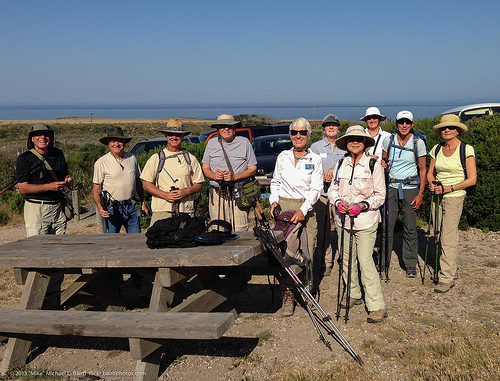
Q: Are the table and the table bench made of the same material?
A: Yes, both the table and the bench are made of wood.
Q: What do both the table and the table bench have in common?
A: The material, both the table and the bench are wooden.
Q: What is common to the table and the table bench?
A: The material, both the table and the bench are wooden.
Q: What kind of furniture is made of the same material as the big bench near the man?
A: The table is made of the same material as the bench.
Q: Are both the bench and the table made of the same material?
A: Yes, both the bench and the table are made of wood.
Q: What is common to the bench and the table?
A: The material, both the bench and the table are wooden.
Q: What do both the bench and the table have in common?
A: The material, both the bench and the table are wooden.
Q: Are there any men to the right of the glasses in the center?
A: Yes, there is a man to the right of the glasses.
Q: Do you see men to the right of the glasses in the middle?
A: Yes, there is a man to the right of the glasses.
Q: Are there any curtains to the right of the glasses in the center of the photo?
A: No, there is a man to the right of the glasses.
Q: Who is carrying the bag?
A: The man is carrying the bag.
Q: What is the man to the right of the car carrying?
A: The man is carrying a bag.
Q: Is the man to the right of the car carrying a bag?
A: Yes, the man is carrying a bag.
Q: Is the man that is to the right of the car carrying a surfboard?
A: No, the man is carrying a bag.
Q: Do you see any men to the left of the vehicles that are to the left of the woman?
A: Yes, there is a man to the left of the vehicles.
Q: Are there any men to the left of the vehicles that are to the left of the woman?
A: Yes, there is a man to the left of the vehicles.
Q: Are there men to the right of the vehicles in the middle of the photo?
A: No, the man is to the left of the vehicles.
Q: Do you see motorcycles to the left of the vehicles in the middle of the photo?
A: No, there is a man to the left of the vehicles.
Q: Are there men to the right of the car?
A: Yes, there is a man to the right of the car.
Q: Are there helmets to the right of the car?
A: No, there is a man to the right of the car.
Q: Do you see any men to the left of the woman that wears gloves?
A: Yes, there is a man to the left of the woman.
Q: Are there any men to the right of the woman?
A: No, the man is to the left of the woman.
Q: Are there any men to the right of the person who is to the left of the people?
A: No, the man is to the left of the woman.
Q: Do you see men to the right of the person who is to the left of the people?
A: No, the man is to the left of the woman.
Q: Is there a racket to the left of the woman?
A: No, there is a man to the left of the woman.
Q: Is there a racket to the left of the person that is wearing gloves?
A: No, there is a man to the left of the woman.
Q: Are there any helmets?
A: No, there are no helmets.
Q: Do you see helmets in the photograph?
A: No, there are no helmets.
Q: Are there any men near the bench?
A: Yes, there is a man near the bench.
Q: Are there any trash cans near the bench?
A: No, there is a man near the bench.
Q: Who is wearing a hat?
A: The man is wearing a hat.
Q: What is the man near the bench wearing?
A: The man is wearing a hat.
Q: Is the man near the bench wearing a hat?
A: Yes, the man is wearing a hat.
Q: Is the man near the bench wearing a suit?
A: No, the man is wearing a hat.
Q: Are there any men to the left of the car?
A: Yes, there is a man to the left of the car.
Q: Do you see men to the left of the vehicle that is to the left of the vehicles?
A: Yes, there is a man to the left of the car.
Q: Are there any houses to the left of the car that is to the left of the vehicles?
A: No, there is a man to the left of the car.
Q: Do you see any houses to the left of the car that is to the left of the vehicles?
A: No, there is a man to the left of the car.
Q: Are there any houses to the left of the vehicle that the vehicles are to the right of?
A: No, there is a man to the left of the car.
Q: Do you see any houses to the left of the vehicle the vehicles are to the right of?
A: No, there is a man to the left of the car.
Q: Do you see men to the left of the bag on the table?
A: Yes, there is a man to the left of the bag.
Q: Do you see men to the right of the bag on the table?
A: No, the man is to the left of the bag.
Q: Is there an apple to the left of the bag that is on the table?
A: No, there is a man to the left of the bag.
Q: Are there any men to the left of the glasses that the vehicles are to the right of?
A: Yes, there is a man to the left of the glasses.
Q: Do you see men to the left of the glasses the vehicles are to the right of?
A: Yes, there is a man to the left of the glasses.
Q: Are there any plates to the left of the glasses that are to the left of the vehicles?
A: No, there is a man to the left of the glasses.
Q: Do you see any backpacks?
A: Yes, there is a backpack.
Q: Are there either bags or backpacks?
A: Yes, there is a backpack.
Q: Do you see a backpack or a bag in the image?
A: Yes, there is a backpack.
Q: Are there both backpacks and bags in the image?
A: Yes, there are both a backpack and a bag.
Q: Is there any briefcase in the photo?
A: No, there are no briefcases.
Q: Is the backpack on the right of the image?
A: Yes, the backpack is on the right of the image.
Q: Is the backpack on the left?
A: No, the backpack is on the right of the image.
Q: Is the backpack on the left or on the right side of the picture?
A: The backpack is on the right of the image.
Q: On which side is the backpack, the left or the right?
A: The backpack is on the right of the image.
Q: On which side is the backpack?
A: The backpack is on the right of the image.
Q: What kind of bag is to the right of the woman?
A: The bag is a backpack.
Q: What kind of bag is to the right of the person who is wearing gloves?
A: The bag is a backpack.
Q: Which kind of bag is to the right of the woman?
A: The bag is a backpack.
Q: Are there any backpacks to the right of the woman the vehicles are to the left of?
A: Yes, there is a backpack to the right of the woman.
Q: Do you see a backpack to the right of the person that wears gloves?
A: Yes, there is a backpack to the right of the woman.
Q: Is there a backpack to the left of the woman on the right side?
A: No, the backpack is to the right of the woman.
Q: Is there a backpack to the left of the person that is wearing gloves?
A: No, the backpack is to the right of the woman.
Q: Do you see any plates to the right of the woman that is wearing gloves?
A: No, there is a backpack to the right of the woman.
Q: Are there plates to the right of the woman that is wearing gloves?
A: No, there is a backpack to the right of the woman.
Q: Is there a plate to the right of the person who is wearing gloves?
A: No, there is a backpack to the right of the woman.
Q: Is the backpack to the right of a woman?
A: Yes, the backpack is to the right of a woman.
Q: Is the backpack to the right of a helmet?
A: No, the backpack is to the right of a woman.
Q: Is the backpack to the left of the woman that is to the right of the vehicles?
A: No, the backpack is to the right of the woman.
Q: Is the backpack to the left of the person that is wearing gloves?
A: No, the backpack is to the right of the woman.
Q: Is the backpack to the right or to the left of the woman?
A: The backpack is to the right of the woman.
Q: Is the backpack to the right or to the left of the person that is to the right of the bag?
A: The backpack is to the right of the woman.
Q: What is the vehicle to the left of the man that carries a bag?
A: The vehicle is a car.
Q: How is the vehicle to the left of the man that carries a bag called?
A: The vehicle is a car.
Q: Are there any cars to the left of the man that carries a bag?
A: Yes, there is a car to the left of the man.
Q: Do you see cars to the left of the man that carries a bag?
A: Yes, there is a car to the left of the man.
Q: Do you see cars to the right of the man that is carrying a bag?
A: No, the car is to the left of the man.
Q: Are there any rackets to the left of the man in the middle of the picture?
A: No, there is a car to the left of the man.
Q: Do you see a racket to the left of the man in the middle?
A: No, there is a car to the left of the man.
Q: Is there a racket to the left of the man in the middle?
A: No, there is a car to the left of the man.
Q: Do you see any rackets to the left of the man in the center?
A: No, there is a car to the left of the man.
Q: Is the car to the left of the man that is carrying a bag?
A: Yes, the car is to the left of the man.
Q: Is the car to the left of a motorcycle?
A: No, the car is to the left of the man.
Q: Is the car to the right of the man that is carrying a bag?
A: No, the car is to the left of the man.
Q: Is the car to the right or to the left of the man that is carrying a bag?
A: The car is to the left of the man.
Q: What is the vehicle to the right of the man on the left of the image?
A: The vehicle is a car.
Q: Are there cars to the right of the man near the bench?
A: Yes, there is a car to the right of the man.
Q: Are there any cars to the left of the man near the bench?
A: No, the car is to the right of the man.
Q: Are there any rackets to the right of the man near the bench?
A: No, there is a car to the right of the man.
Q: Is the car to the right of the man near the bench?
A: Yes, the car is to the right of the man.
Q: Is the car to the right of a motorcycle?
A: No, the car is to the right of the man.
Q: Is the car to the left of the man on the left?
A: No, the car is to the right of the man.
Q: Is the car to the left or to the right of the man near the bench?
A: The car is to the right of the man.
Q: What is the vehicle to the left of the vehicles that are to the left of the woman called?
A: The vehicle is a car.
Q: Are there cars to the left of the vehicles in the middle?
A: Yes, there is a car to the left of the vehicles.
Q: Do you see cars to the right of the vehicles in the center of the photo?
A: No, the car is to the left of the vehicles.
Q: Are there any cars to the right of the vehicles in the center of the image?
A: No, the car is to the left of the vehicles.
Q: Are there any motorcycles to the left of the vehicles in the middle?
A: No, there is a car to the left of the vehicles.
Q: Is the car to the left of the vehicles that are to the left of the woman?
A: Yes, the car is to the left of the vehicles.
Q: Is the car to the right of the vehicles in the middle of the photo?
A: No, the car is to the left of the vehicles.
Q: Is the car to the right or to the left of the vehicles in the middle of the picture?
A: The car is to the left of the vehicles.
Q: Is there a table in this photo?
A: Yes, there is a table.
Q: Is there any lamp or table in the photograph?
A: Yes, there is a table.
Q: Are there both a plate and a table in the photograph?
A: No, there is a table but no plates.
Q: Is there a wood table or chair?
A: Yes, there is a wood table.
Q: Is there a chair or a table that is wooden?
A: Yes, the table is wooden.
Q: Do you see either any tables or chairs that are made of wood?
A: Yes, the table is made of wood.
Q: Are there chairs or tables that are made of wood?
A: Yes, the table is made of wood.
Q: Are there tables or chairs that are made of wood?
A: Yes, the table is made of wood.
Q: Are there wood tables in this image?
A: Yes, there is a wood table.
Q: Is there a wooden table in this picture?
A: Yes, there is a wood table.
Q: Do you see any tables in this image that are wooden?
A: Yes, there is a table that is wooden.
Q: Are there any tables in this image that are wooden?
A: Yes, there is a table that is wooden.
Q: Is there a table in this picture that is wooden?
A: Yes, there is a table that is wooden.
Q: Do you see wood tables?
A: Yes, there is a table that is made of wood.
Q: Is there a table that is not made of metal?
A: Yes, there is a table that is made of wood.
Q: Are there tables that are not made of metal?
A: Yes, there is a table that is made of wood.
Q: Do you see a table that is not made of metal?
A: Yes, there is a table that is made of wood.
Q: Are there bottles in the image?
A: No, there are no bottles.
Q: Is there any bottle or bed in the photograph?
A: No, there are no bottles or beds.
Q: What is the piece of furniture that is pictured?
A: The piece of furniture is a table.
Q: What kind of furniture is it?
A: The piece of furniture is a table.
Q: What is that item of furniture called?
A: This is a table.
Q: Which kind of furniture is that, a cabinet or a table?
A: This is a table.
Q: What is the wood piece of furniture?
A: The piece of furniture is a table.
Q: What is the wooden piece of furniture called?
A: The piece of furniture is a table.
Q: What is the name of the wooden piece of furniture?
A: The piece of furniture is a table.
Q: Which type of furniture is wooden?
A: The furniture is a table.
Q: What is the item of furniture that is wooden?
A: The piece of furniture is a table.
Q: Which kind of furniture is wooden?
A: The furniture is a table.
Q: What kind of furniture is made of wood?
A: The furniture is a table.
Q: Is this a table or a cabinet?
A: This is a table.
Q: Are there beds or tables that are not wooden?
A: No, there is a table but it is wooden.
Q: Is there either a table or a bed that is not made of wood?
A: No, there is a table but it is made of wood.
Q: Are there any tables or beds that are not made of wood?
A: No, there is a table but it is made of wood.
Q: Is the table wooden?
A: Yes, the table is wooden.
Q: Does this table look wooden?
A: Yes, the table is wooden.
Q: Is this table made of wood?
A: Yes, the table is made of wood.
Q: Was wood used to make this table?
A: Yes, the table is made of wood.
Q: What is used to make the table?
A: The table is made of wood.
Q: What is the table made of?
A: The table is made of wood.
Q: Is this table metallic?
A: No, the table is wooden.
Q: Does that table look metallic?
A: No, the table is wooden.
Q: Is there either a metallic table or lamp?
A: No, there is a table but it is wooden.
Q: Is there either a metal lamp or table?
A: No, there is a table but it is wooden.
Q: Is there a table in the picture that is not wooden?
A: No, there is a table but it is wooden.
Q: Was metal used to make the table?
A: No, the table is made of wood.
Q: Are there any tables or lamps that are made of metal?
A: No, there is a table but it is made of wood.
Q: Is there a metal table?
A: No, there is a table but it is made of wood.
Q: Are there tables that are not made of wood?
A: No, there is a table but it is made of wood.